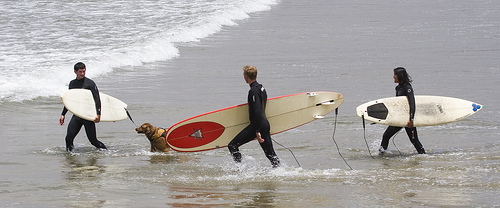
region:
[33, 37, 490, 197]
three people holding surf boards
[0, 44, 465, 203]
three people walking in water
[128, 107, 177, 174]
a dog in the water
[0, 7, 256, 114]
a wave in the water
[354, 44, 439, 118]
a woman with black hair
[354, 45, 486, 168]
a woman holding a surfboard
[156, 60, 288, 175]
a man holding a surf board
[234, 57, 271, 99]
a man with blonde hair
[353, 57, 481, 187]
a woman walking in water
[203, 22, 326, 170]
a man walking in water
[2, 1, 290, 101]
The wave is white.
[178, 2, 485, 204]
The water is blue.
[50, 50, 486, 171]
Three surfers in the water.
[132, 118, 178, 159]
One dog in the water.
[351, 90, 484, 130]
The surf board is white.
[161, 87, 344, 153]
The surfboard is tan and red.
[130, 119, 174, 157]
The dog is brown.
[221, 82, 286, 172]
The wetsuit is black.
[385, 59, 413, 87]
The man has long hair.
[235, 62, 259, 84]
The man is blonde.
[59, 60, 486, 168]
three surfers walking into the ocean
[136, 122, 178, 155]
a brown dog walking on the shore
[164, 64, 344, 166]
a blonde surfer with a red and white surfboard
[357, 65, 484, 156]
a woman with dark hair holding a white surfboard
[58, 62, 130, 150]
a man with dark hair holding a white surfboard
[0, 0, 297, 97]
ocean waves breaking on the shore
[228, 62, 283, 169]
a man in a wetsuit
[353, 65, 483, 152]
a female surfer wearing a wetsuit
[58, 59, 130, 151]
a male surfer wearing a wetsuit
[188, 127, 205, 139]
a surfboard logo on the bottom of the surfboard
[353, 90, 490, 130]
A WHITE SURFBOARD WITH A BLACK FIN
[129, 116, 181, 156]
A BROWN DOG IN A BLACK HARNESS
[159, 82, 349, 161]
A RED, WHITE, AND BLACK SURFBOARD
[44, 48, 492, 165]
THREE SURFERS WALKING IN WATER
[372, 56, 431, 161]
A BRUNETTE WOMAN IN A BLACK SURFING SUIT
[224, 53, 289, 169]
A BLONDE HAIRED MAN IN A BLACK SURF SUIT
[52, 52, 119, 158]
A BRUNETTE MAN IN A BLACK SURF SUIT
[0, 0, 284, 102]
A SMALL WAVE WASHING ONTO SHORE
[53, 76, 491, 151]
THREE DIFFERENTLY SIZED SURFBOARDS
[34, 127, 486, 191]
SPLASHING FROM PEOPLE WALKING THROUGH WATER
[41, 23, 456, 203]
there are three surfers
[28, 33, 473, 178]
the beach is sandy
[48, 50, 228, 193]
the first surfer has a dog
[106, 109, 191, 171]
this is a golden retriever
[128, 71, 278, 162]
the surfboard is white and red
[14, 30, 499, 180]
the wetsuits are black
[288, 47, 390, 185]
the surfboard has three fins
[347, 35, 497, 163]
he has long hair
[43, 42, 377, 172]
there is one dog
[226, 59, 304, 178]
this man is blonde